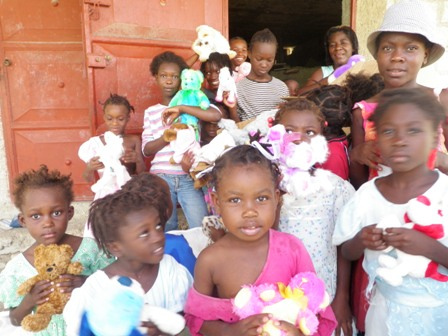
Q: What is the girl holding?
A: Stuffed animal.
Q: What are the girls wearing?
A: Shirts.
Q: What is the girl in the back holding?
A: Green bear.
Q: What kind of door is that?
A: A metal door.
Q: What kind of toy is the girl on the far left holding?
A: A brown teddy bear.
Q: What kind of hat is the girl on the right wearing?
A: A white large hat.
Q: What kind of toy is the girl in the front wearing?
A: A pink teddy bear.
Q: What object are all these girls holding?
A: Teddy bears.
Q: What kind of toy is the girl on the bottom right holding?
A: A red and white animal toy.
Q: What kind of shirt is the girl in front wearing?
A: A pink shirt.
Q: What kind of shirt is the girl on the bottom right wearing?
A: A white shirt.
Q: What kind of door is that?
A: A large red metal door.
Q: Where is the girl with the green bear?
A: By the door.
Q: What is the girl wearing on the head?
A: A hat.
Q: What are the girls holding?
A: Stuffed animals.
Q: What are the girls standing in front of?
A: Entrance.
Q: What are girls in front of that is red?
A: Door.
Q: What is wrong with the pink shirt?
A: To big.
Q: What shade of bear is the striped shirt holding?
A: Teal bear.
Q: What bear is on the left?
A: Brown bear.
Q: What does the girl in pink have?
A: Pink and white bear.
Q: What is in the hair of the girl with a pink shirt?
A: Pink and white ribbon.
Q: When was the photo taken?
A: Day time.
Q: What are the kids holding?
A: Bears.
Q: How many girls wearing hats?
A: One.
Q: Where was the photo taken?
A: At a school.